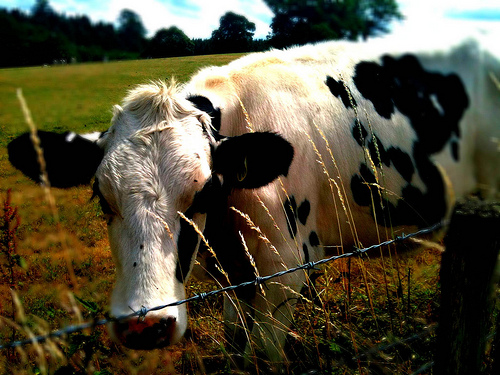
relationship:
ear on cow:
[210, 125, 298, 193] [7, 13, 498, 363]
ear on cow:
[9, 110, 105, 205] [7, 13, 498, 363]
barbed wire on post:
[3, 218, 456, 350] [435, 194, 497, 354]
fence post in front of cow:
[437, 184, 496, 373] [7, 13, 498, 363]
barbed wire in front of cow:
[11, 207, 463, 336] [7, 13, 498, 363]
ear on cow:
[1, 127, 106, 189] [7, 13, 498, 363]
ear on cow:
[210, 131, 295, 194] [7, 13, 498, 363]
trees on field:
[0, 0, 407, 67] [4, 42, 497, 372]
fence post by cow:
[437, 184, 496, 373] [26, 42, 372, 372]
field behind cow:
[5, 41, 461, 348] [122, 86, 267, 205]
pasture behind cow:
[9, 58, 420, 335] [7, 13, 498, 363]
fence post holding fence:
[437, 184, 496, 373] [239, 257, 440, 340]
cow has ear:
[7, 13, 498, 363] [210, 131, 295, 194]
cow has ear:
[7, 13, 498, 363] [1, 127, 106, 189]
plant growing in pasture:
[28, 200, 162, 350] [5, 50, 149, 310]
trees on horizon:
[18, 14, 190, 51] [0, 49, 234, 63]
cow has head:
[7, 13, 498, 363] [51, 100, 243, 349]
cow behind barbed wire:
[7, 13, 498, 363] [3, 218, 456, 350]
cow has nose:
[7, 13, 498, 363] [116, 312, 176, 336]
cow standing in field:
[7, 13, 498, 363] [30, 46, 482, 346]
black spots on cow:
[319, 52, 472, 229] [9, 40, 499, 354]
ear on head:
[1, 127, 106, 189] [5, 79, 295, 349]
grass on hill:
[4, 54, 211, 123] [11, 52, 141, 92]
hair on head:
[116, 73, 199, 127] [0, 102, 294, 357]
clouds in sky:
[394, 2, 438, 23] [20, 4, 480, 17]